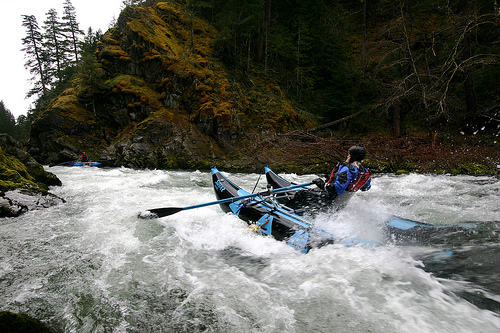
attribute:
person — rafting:
[296, 139, 374, 225]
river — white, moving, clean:
[73, 171, 486, 324]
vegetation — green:
[428, 157, 486, 172]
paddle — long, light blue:
[138, 202, 196, 224]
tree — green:
[17, 0, 90, 85]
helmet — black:
[350, 149, 362, 158]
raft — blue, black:
[221, 184, 315, 240]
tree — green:
[1, 105, 21, 132]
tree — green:
[288, 25, 307, 93]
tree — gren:
[239, 10, 266, 71]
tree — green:
[329, 15, 358, 72]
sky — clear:
[5, 13, 28, 92]